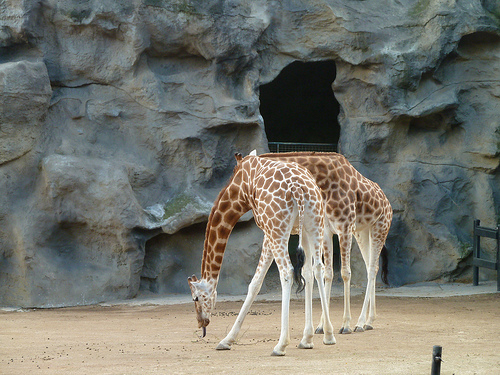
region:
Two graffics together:
[183, 145, 397, 358]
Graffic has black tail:
[292, 247, 303, 291]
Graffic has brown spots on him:
[200, 168, 323, 280]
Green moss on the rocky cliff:
[154, 189, 205, 220]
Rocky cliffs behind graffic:
[7, 50, 476, 297]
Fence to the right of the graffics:
[470, 213, 499, 286]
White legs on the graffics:
[215, 272, 379, 354]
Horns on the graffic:
[183, 273, 200, 296]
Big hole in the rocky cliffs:
[240, 43, 358, 163]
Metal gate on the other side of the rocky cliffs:
[267, 138, 342, 156]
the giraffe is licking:
[181, 162, 395, 373]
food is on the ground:
[99, 314, 188, 369]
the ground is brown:
[104, 317, 161, 374]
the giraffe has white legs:
[226, 287, 312, 352]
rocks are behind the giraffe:
[115, 213, 225, 323]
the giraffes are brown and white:
[194, 140, 412, 308]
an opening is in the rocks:
[230, 53, 389, 168]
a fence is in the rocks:
[245, 126, 415, 220]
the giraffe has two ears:
[179, 259, 214, 306]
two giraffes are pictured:
[170, 129, 497, 365]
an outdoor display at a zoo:
[0, 0, 499, 374]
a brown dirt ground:
[0, 290, 499, 373]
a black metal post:
[429, 344, 442, 374]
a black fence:
[471, 218, 498, 290]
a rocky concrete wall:
[0, 0, 498, 312]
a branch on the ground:
[190, 322, 264, 345]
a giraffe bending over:
[185, 154, 335, 356]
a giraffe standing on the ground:
[232, 150, 392, 334]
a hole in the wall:
[256, 58, 341, 153]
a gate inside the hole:
[266, 140, 337, 152]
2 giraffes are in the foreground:
[172, 147, 391, 359]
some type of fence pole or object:
[432, 344, 447, 374]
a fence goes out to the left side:
[466, 215, 496, 290]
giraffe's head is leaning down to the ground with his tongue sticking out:
[171, 261, 217, 341]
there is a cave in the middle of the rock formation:
[248, 38, 349, 149]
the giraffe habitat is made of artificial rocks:
[3, 2, 245, 140]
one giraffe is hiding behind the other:
[178, 144, 393, 360]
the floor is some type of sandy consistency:
[2, 312, 164, 369]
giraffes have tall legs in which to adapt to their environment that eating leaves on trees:
[216, 270, 389, 353]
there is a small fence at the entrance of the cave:
[256, 138, 342, 153]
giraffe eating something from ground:
[172, 138, 395, 361]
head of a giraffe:
[179, 260, 224, 340]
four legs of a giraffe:
[204, 225, 342, 355]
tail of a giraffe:
[283, 189, 316, 287]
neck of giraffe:
[194, 165, 254, 281]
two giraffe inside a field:
[178, 141, 402, 357]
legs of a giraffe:
[323, 233, 389, 335]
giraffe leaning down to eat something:
[170, 129, 344, 359]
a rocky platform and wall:
[0, 5, 177, 292]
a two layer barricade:
[459, 210, 499, 285]